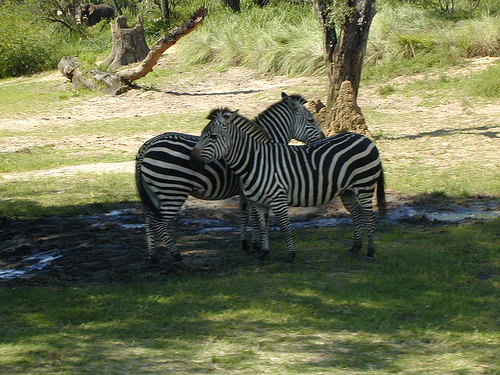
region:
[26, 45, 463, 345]
Two zebras standing in the shade.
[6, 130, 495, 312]
Water runnig through a field.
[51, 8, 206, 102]
Trunk and limbs of a dead tree.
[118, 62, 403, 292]
Two zebras standing close to each other.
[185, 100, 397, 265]
Zebra facing to the left.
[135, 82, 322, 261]
Zebra facing to the right.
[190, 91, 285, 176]
Mane on both zebras' necks.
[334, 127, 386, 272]
Back legs of zebra in front.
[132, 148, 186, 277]
Back legs of zebra in in the back.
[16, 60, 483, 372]
Field has green and brown grass.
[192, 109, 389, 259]
black and white zebra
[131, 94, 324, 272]
zebra standing in grass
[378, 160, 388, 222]
black tail of zebra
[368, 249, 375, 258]
black hoof on zebra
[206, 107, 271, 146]
white and black zebra mane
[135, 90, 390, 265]
two zebra on grass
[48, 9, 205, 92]
broken tree branch on ground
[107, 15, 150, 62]
broken tree stump on ground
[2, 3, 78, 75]
green plants on ground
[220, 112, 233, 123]
white ear of zebra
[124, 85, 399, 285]
two zebras in a field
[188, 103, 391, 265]
black and white striped zebra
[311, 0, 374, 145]
a tree trunk behind a zebra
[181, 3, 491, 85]
long grass in a zebra enclosure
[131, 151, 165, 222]
black and white zebra tail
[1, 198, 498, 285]
wet muddy trail under some zebras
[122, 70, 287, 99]
shadow of a tree branch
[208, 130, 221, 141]
black eye of a zebra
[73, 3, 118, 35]
an elephant in the background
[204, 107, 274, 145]
fluffy black and white mane of a zebra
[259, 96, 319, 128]
black and white zebra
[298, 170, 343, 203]
black and white stripes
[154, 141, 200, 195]
black and white stripes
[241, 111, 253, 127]
thick mane of zebra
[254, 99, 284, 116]
thick mane of zebra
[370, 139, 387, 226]
black tail of zebra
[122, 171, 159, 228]
black tail of zebra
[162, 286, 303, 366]
green grass growing on ground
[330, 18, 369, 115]
tree trunk behind zebras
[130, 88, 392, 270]
Two zebra are next to each other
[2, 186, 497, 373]
Shadows on the grass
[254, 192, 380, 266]
Four legs on a zebra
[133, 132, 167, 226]
Tail of a zebra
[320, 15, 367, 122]
A brown tree trunk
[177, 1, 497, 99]
The grass is long and green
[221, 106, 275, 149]
Mane on zebra's neck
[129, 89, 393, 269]
The zebra have black and white stripes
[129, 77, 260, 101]
Tree's shadow on the grass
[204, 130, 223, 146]
A black eye of a zebra